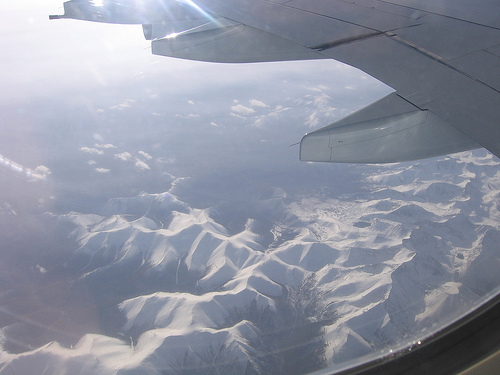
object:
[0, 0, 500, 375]
snow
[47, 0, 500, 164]
airplane wing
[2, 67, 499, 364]
white mountains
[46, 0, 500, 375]
airplane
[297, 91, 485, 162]
metal cover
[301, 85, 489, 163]
plane engine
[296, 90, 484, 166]
plane wing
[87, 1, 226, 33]
light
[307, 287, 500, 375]
strip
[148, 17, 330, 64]
plane wing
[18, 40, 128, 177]
sky/mountains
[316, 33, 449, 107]
rectangular tile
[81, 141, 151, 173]
clouds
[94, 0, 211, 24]
sun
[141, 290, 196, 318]
ice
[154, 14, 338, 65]
wing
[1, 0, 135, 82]
sky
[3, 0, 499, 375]
window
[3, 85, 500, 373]
mountain range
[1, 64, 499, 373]
mountain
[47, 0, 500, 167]
roof